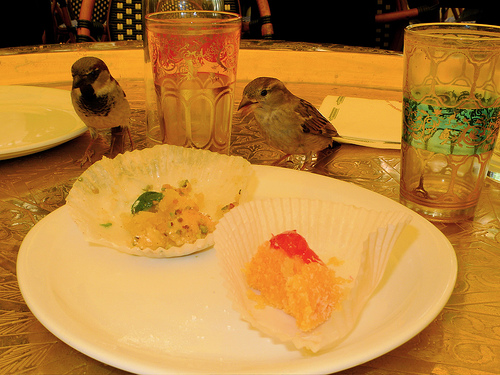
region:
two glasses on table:
[145, 9, 497, 222]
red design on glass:
[153, 30, 237, 89]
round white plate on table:
[16, 156, 457, 373]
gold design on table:
[0, 159, 82, 373]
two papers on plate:
[65, 142, 410, 358]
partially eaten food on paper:
[247, 232, 341, 336]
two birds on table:
[72, 53, 333, 172]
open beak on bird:
[236, 97, 260, 122]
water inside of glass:
[156, 71, 234, 144]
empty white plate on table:
[0, 83, 87, 156]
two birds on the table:
[52, 32, 347, 182]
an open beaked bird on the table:
[236, 72, 342, 170]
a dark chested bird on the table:
[68, 54, 140, 154]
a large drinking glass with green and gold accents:
[394, 24, 499, 234]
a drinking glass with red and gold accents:
[138, 22, 241, 150]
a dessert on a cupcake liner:
[214, 193, 412, 350]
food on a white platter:
[16, 140, 473, 370]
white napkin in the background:
[318, 86, 424, 155]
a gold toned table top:
[401, 218, 497, 372]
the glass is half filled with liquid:
[141, 9, 252, 154]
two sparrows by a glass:
[67, 56, 336, 166]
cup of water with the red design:
[148, 11, 237, 150]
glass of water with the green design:
[403, 20, 498, 225]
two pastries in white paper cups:
[71, 150, 409, 360]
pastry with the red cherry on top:
[243, 230, 338, 330]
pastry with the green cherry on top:
[129, 185, 207, 249]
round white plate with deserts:
[19, 160, 455, 374]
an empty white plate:
[0, 84, 87, 163]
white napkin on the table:
[315, 90, 405, 150]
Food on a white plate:
[218, 208, 403, 370]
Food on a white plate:
[72, 145, 221, 245]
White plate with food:
[11, 177, 429, 371]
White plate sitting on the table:
[35, 183, 465, 373]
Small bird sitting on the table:
[244, 70, 339, 160]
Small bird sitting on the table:
[60, 51, 142, 141]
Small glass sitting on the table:
[398, 15, 485, 232]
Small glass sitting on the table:
[143, 8, 250, 171]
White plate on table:
[5, 69, 76, 164]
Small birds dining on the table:
[68, 37, 356, 194]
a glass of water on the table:
[141, 1, 246, 158]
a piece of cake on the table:
[235, 225, 360, 340]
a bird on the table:
[60, 50, 165, 155]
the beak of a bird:
[230, 91, 250, 108]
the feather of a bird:
[297, 90, 347, 145]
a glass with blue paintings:
[396, 75, 493, 170]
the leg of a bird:
[61, 135, 96, 165]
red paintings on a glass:
[155, 21, 240, 79]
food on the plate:
[125, 180, 215, 250]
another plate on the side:
[2, 58, 65, 158]